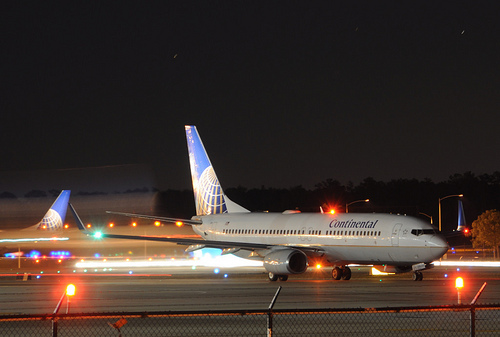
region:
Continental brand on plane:
[327, 217, 386, 229]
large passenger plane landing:
[100, 122, 448, 285]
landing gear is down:
[263, 260, 431, 285]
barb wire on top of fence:
[89, 291, 481, 306]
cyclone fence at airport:
[280, 315, 438, 335]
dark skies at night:
[329, 38, 449, 145]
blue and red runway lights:
[35, 256, 180, 275]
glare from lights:
[1, 165, 163, 216]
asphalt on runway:
[111, 285, 237, 306]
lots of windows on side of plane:
[223, 226, 385, 241]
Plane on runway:
[102, 121, 450, 290]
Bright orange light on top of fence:
[452, 272, 467, 302]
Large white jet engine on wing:
[260, 246, 307, 275]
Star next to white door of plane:
[401, 225, 408, 236]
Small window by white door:
[376, 227, 382, 236]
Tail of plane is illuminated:
[180, 119, 232, 215]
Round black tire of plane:
[329, 264, 341, 279]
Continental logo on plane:
[327, 217, 381, 228]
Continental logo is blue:
[327, 215, 384, 229]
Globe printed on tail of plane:
[194, 162, 225, 214]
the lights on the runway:
[50, 266, 491, 304]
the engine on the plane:
[240, 242, 310, 279]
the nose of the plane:
[430, 235, 450, 257]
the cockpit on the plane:
[405, 222, 441, 232]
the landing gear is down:
[257, 255, 428, 287]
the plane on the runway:
[105, 112, 455, 312]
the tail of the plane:
[176, 110, 231, 210]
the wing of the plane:
[90, 222, 327, 259]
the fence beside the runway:
[28, 295, 493, 332]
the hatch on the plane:
[388, 225, 401, 249]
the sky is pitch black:
[282, 50, 459, 148]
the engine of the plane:
[237, 241, 330, 284]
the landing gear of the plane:
[240, 259, 432, 286]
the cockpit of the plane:
[396, 225, 444, 242]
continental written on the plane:
[311, 203, 393, 242]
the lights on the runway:
[6, 230, 241, 285]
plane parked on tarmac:
[147, 115, 457, 291]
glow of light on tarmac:
[440, 265, 470, 295]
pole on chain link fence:
[245, 280, 300, 330]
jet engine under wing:
[255, 247, 311, 278]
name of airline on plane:
[322, 214, 381, 241]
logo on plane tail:
[185, 131, 220, 222]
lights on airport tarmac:
[50, 250, 155, 278]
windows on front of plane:
[405, 222, 442, 242]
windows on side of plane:
[262, 225, 325, 239]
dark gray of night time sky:
[291, 57, 394, 138]